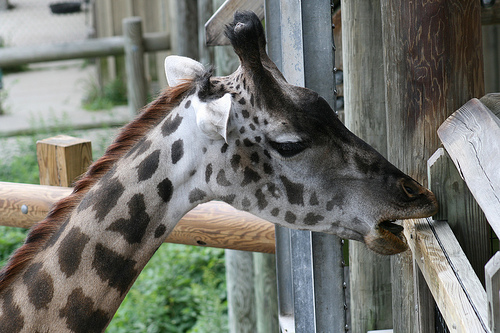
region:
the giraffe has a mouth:
[1, 12, 441, 332]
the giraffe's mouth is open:
[357, 198, 447, 252]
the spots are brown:
[80, 186, 150, 272]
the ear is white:
[190, 97, 240, 137]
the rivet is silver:
[17, 203, 32, 213]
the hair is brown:
[1, 58, 181, 283]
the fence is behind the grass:
[5, 11, 173, 157]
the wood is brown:
[345, 3, 478, 100]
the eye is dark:
[266, 130, 312, 160]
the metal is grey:
[261, 4, 341, 89]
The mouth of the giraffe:
[375, 198, 435, 249]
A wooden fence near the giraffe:
[2, 136, 279, 254]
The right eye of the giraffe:
[268, 137, 306, 158]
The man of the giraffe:
[0, 78, 193, 281]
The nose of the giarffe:
[396, 173, 434, 211]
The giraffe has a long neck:
[1, 102, 196, 332]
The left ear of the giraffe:
[164, 53, 204, 84]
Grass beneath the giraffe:
[1, 145, 226, 332]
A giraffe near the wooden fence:
[2, 17, 434, 332]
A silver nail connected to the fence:
[20, 203, 29, 213]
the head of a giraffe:
[170, 30, 432, 266]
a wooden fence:
[385, 80, 488, 319]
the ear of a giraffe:
[172, 27, 237, 120]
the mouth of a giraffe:
[361, 177, 420, 257]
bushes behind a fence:
[149, 259, 213, 311]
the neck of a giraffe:
[13, 53, 228, 323]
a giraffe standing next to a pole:
[19, 39, 461, 327]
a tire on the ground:
[43, 3, 91, 18]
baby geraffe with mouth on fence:
[0, 9, 435, 331]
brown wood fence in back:
[1, 181, 277, 254]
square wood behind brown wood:
[35, 132, 95, 186]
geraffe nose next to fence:
[380, 176, 442, 218]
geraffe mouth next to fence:
[365, 170, 437, 259]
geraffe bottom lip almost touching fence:
[363, 226, 410, 253]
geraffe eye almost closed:
[268, 133, 310, 160]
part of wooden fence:
[402, 218, 498, 331]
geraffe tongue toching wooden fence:
[384, 220, 404, 235]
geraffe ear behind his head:
[159, 54, 216, 84]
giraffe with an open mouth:
[7, 12, 434, 322]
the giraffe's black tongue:
[381, 224, 402, 234]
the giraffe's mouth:
[375, 210, 432, 256]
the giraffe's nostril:
[400, 180, 417, 195]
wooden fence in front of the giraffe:
[405, 99, 495, 331]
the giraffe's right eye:
[267, 138, 309, 158]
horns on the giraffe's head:
[227, 10, 277, 91]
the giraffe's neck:
[1, 96, 193, 331]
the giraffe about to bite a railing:
[9, 16, 436, 331]